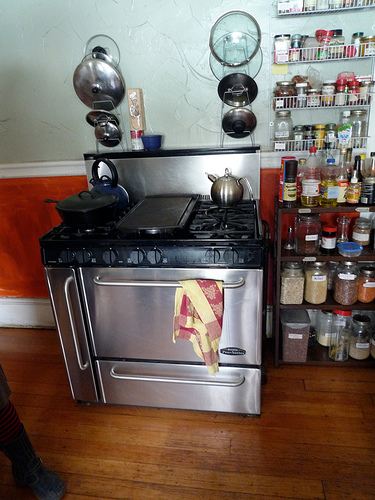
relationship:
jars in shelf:
[280, 266, 374, 363] [269, 245, 374, 273]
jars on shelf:
[280, 266, 374, 363] [269, 245, 374, 273]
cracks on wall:
[143, 30, 217, 135] [19, 47, 60, 113]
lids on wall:
[207, 4, 274, 154] [19, 47, 60, 113]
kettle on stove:
[196, 162, 246, 217] [189, 208, 246, 247]